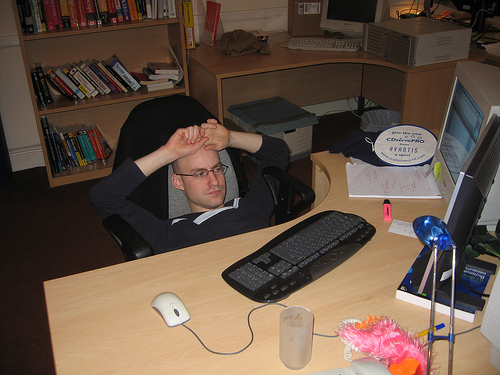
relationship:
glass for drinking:
[278, 306, 313, 370] [282, 307, 311, 328]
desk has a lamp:
[43, 151, 499, 374] [413, 216, 458, 374]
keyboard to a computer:
[220, 211, 377, 305] [418, 111, 497, 292]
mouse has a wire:
[153, 293, 189, 327] [181, 301, 479, 355]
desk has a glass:
[43, 151, 499, 374] [278, 306, 313, 370]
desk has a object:
[43, 151, 499, 374] [333, 315, 438, 374]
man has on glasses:
[92, 117, 289, 254] [177, 164, 230, 180]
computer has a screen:
[418, 111, 497, 292] [439, 80, 483, 188]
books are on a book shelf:
[30, 48, 186, 111] [12, 2, 191, 190]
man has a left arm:
[92, 117, 289, 254] [91, 124, 209, 255]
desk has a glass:
[43, 151, 499, 374] [274, 304, 317, 373]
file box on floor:
[229, 96, 318, 163] [2, 106, 397, 374]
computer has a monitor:
[418, 111, 497, 292] [419, 113, 499, 295]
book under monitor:
[394, 242, 490, 323] [419, 113, 499, 295]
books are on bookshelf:
[30, 48, 186, 111] [12, 1, 191, 191]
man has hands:
[92, 117, 289, 254] [167, 126, 207, 157]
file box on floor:
[228, 95, 319, 168] [2, 106, 397, 374]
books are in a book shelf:
[30, 48, 186, 111] [12, 2, 191, 190]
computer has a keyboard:
[418, 111, 497, 292] [220, 211, 377, 305]